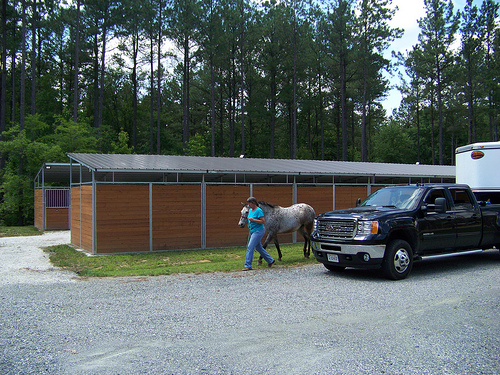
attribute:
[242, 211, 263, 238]
shirt — blue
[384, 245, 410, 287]
tire — black , rubber 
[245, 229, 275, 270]
jeans — blue, denim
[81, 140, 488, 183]
roof — metal, long 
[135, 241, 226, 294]
grass — green 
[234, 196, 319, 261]
horse — white , gray 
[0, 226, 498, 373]
road — dirt 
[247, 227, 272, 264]
jeans — blue 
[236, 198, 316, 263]
horse — white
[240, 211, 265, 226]
shirt — blue 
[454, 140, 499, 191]
trailer — white 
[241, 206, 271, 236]
t shirt — blue , light 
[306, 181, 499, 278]
truck — black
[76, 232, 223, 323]
grassy area — small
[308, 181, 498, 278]
pickup truck — black 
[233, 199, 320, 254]
horse — white 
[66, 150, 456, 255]
pen — wooden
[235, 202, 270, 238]
shirt — blue 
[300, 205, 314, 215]
spots — brown